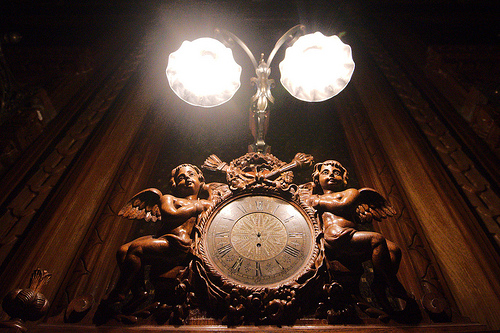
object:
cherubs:
[105, 148, 420, 324]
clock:
[172, 177, 361, 313]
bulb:
[184, 46, 224, 91]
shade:
[157, 34, 245, 112]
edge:
[276, 26, 364, 113]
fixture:
[145, 16, 367, 209]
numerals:
[216, 199, 304, 280]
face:
[198, 190, 320, 284]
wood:
[189, 148, 332, 321]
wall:
[1, 1, 499, 332]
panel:
[0, 1, 499, 332]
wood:
[17, 10, 480, 311]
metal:
[206, 17, 309, 158]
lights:
[154, 21, 375, 118]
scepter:
[197, 146, 317, 190]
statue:
[4, 261, 54, 325]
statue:
[108, 153, 216, 314]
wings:
[119, 186, 200, 225]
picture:
[0, 0, 500, 333]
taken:
[10, 9, 463, 251]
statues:
[103, 148, 415, 317]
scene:
[0, 1, 499, 332]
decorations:
[86, 140, 425, 331]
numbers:
[205, 197, 320, 294]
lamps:
[153, 25, 363, 121]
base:
[105, 289, 405, 331]